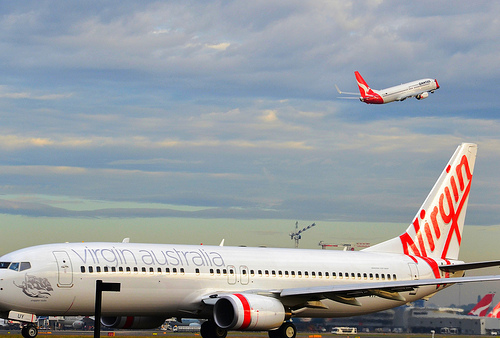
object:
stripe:
[232, 293, 251, 327]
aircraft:
[335, 71, 441, 105]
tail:
[353, 71, 374, 98]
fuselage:
[378, 78, 433, 102]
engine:
[212, 293, 287, 333]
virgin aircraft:
[0, 142, 500, 337]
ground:
[1, 325, 497, 336]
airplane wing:
[269, 275, 499, 298]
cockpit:
[0, 242, 74, 317]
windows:
[20, 262, 32, 272]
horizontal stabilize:
[439, 259, 500, 273]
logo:
[12, 273, 53, 302]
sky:
[3, 5, 497, 262]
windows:
[80, 266, 85, 274]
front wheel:
[24, 324, 44, 337]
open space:
[40, 316, 92, 337]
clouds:
[9, 4, 496, 84]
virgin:
[399, 155, 472, 281]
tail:
[360, 142, 480, 264]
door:
[52, 250, 74, 285]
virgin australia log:
[71, 245, 227, 267]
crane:
[319, 241, 356, 252]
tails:
[467, 294, 493, 317]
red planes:
[466, 294, 500, 318]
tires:
[267, 322, 296, 338]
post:
[295, 221, 299, 248]